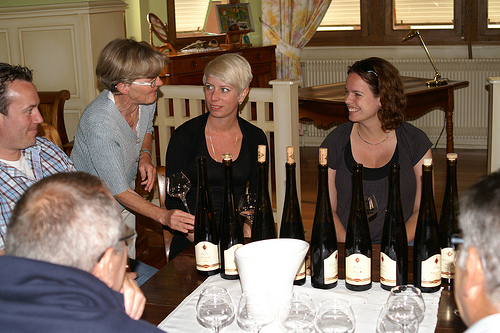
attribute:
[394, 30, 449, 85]
lamp — brass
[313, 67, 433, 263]
woman — smiling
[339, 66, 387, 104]
sunglasses — black 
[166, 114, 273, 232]
shirt — black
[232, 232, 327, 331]
bucket — white, tall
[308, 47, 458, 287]
woman — smiling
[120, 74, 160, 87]
glasses — silver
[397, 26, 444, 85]
lamp — shiny, desk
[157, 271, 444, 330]
tablecloth — white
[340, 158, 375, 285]
bottle — open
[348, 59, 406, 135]
hair — black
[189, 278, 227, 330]
wine glass — empty 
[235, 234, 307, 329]
vase — white 